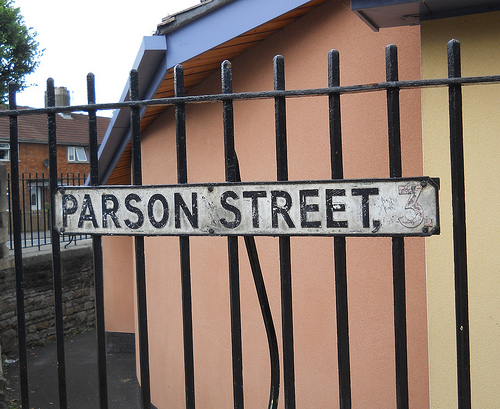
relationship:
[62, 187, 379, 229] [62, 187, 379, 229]
parson street says parson street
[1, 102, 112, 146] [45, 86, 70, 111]
roof has chimney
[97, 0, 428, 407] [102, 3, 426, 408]
building has a wall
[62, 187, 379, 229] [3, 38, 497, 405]
parson street on gate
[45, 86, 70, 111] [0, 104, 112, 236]
chimney on building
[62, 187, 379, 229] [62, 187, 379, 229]
parson street on parson street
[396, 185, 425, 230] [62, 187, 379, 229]
number on parson street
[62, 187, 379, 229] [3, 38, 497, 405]
parson street attached to fence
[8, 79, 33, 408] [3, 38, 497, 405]
rod on fence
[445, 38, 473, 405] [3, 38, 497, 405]
rod on fence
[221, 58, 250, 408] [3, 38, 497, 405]
rod on fence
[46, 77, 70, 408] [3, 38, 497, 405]
rod on fence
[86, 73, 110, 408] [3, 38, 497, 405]
rod on fence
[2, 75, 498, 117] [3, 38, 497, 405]
pole on fence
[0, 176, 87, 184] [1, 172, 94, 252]
pole on fence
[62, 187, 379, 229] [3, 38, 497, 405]
parson street on fence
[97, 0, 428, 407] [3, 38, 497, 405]
house behind gate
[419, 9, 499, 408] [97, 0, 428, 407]
wall next to house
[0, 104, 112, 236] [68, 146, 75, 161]
house has window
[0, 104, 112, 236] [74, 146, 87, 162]
house has window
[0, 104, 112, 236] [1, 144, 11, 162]
house has window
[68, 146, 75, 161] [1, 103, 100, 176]
window on top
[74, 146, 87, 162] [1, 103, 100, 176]
window on top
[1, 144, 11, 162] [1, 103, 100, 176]
window on top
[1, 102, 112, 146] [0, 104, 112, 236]
roof on house